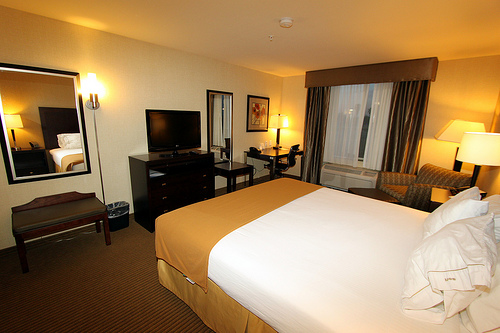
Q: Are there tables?
A: Yes, there is a table.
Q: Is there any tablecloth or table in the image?
A: Yes, there is a table.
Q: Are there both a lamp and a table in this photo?
A: Yes, there are both a table and a lamp.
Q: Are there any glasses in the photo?
A: No, there are no glasses.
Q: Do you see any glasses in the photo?
A: No, there are no glasses.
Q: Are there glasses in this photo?
A: No, there are no glasses.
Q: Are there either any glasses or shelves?
A: No, there are no glasses or shelves.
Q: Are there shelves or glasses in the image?
A: No, there are no glasses or shelves.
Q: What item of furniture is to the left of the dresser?
A: The piece of furniture is a table.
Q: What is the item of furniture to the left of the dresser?
A: The piece of furniture is a table.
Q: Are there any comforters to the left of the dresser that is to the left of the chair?
A: No, there is a table to the left of the dresser.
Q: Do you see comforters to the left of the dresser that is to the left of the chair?
A: No, there is a table to the left of the dresser.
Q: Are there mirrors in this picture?
A: Yes, there is a mirror.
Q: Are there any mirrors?
A: Yes, there is a mirror.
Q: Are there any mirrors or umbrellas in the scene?
A: Yes, there is a mirror.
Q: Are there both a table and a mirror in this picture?
A: Yes, there are both a mirror and a table.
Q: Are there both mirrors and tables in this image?
A: Yes, there are both a mirror and a table.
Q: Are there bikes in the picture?
A: No, there are no bikes.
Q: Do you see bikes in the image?
A: No, there are no bikes.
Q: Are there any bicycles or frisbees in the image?
A: No, there are no bicycles or frisbees.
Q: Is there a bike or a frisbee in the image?
A: No, there are no bikes or frisbees.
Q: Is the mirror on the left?
A: Yes, the mirror is on the left of the image.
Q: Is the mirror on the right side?
A: No, the mirror is on the left of the image.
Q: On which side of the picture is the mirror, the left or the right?
A: The mirror is on the left of the image.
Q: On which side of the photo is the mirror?
A: The mirror is on the left of the image.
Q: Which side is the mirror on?
A: The mirror is on the left of the image.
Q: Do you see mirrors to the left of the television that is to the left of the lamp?
A: Yes, there is a mirror to the left of the television.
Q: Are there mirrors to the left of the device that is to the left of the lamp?
A: Yes, there is a mirror to the left of the television.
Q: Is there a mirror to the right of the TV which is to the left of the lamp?
A: No, the mirror is to the left of the television.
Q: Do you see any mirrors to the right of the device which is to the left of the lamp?
A: No, the mirror is to the left of the television.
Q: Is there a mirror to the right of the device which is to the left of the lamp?
A: No, the mirror is to the left of the television.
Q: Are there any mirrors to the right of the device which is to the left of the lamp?
A: No, the mirror is to the left of the television.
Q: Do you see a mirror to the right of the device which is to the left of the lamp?
A: No, the mirror is to the left of the television.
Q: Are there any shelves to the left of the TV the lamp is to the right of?
A: No, there is a mirror to the left of the television.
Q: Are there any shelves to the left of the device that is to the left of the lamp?
A: No, there is a mirror to the left of the television.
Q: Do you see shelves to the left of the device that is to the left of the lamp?
A: No, there is a mirror to the left of the television.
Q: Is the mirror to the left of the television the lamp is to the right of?
A: Yes, the mirror is to the left of the TV.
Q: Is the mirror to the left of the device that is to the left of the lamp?
A: Yes, the mirror is to the left of the TV.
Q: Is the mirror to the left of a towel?
A: No, the mirror is to the left of the TV.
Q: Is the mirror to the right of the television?
A: No, the mirror is to the left of the television.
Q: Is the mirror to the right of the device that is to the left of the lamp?
A: No, the mirror is to the left of the television.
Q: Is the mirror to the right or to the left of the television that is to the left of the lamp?
A: The mirror is to the left of the TV.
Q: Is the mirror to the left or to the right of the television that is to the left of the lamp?
A: The mirror is to the left of the TV.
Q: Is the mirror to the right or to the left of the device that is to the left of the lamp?
A: The mirror is to the left of the TV.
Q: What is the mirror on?
A: The mirror is on the wall.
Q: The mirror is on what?
A: The mirror is on the wall.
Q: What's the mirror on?
A: The mirror is on the wall.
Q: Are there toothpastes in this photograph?
A: No, there are no toothpastes.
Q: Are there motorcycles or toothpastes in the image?
A: No, there are no toothpastes or motorcycles.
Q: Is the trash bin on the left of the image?
A: Yes, the trash bin is on the left of the image.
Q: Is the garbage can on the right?
A: No, the garbage can is on the left of the image.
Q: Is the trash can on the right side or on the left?
A: The trash can is on the left of the image.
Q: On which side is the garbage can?
A: The garbage can is on the left of the image.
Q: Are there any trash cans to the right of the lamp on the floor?
A: Yes, there is a trash can to the right of the lamp.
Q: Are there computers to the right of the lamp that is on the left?
A: No, there is a trash can to the right of the lamp.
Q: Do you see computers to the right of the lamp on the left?
A: No, there is a trash can to the right of the lamp.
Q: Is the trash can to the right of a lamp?
A: Yes, the trash can is to the right of a lamp.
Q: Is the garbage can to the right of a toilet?
A: No, the garbage can is to the right of a lamp.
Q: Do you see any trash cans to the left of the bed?
A: Yes, there is a trash can to the left of the bed.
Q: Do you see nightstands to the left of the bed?
A: No, there is a trash can to the left of the bed.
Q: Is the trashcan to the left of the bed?
A: Yes, the trashcan is to the left of the bed.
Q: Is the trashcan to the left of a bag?
A: No, the trashcan is to the left of the bed.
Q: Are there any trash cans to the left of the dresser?
A: Yes, there is a trash can to the left of the dresser.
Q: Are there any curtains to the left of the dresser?
A: No, there is a trash can to the left of the dresser.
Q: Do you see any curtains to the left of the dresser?
A: No, there is a trash can to the left of the dresser.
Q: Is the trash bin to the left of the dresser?
A: Yes, the trash bin is to the left of the dresser.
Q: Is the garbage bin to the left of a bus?
A: No, the garbage bin is to the left of the dresser.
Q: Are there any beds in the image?
A: Yes, there is a bed.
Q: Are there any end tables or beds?
A: Yes, there is a bed.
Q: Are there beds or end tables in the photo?
A: Yes, there is a bed.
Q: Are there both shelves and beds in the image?
A: No, there is a bed but no shelves.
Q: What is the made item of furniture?
A: The piece of furniture is a bed.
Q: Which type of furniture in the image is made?
A: The furniture is a bed.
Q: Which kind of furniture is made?
A: The furniture is a bed.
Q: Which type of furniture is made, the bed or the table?
A: The bed is made.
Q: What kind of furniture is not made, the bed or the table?
A: The table is not made.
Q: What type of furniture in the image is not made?
A: The furniture is a table.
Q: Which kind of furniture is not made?
A: The furniture is a table.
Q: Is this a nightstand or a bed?
A: This is a bed.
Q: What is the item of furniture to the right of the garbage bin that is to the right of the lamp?
A: The piece of furniture is a bed.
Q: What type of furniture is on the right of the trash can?
A: The piece of furniture is a bed.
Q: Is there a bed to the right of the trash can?
A: Yes, there is a bed to the right of the trash can.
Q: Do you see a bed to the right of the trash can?
A: Yes, there is a bed to the right of the trash can.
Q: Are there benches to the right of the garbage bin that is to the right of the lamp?
A: No, there is a bed to the right of the trash can.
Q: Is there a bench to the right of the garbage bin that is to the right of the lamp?
A: No, there is a bed to the right of the trash can.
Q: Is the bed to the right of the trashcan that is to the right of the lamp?
A: Yes, the bed is to the right of the trashcan.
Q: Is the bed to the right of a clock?
A: No, the bed is to the right of the trashcan.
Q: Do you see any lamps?
A: Yes, there is a lamp.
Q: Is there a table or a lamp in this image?
A: Yes, there is a lamp.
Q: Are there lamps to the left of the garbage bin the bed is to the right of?
A: Yes, there is a lamp to the left of the trash can.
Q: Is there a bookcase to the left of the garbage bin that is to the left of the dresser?
A: No, there is a lamp to the left of the garbage bin.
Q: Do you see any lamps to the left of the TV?
A: Yes, there is a lamp to the left of the TV.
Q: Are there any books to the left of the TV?
A: No, there is a lamp to the left of the TV.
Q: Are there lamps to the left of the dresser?
A: Yes, there is a lamp to the left of the dresser.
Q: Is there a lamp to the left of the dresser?
A: Yes, there is a lamp to the left of the dresser.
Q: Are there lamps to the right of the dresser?
A: No, the lamp is to the left of the dresser.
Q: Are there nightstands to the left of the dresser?
A: No, there is a lamp to the left of the dresser.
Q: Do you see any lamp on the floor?
A: Yes, there is a lamp on the floor.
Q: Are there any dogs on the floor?
A: No, there is a lamp on the floor.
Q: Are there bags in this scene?
A: No, there are no bags.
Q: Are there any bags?
A: No, there are no bags.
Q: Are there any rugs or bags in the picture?
A: No, there are no bags or rugs.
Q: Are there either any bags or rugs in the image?
A: No, there are no bags or rugs.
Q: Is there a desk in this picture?
A: Yes, there is a desk.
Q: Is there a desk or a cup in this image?
A: Yes, there is a desk.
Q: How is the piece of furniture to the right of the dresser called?
A: The piece of furniture is a desk.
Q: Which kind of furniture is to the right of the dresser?
A: The piece of furniture is a desk.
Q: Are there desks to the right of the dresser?
A: Yes, there is a desk to the right of the dresser.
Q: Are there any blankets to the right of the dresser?
A: No, there is a desk to the right of the dresser.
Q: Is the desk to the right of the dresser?
A: Yes, the desk is to the right of the dresser.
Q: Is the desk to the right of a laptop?
A: No, the desk is to the right of the dresser.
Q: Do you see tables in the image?
A: Yes, there is a table.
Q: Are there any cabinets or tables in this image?
A: Yes, there is a table.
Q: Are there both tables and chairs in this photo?
A: Yes, there are both a table and a chair.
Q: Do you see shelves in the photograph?
A: No, there are no shelves.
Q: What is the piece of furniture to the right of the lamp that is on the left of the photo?
A: The piece of furniture is a dresser.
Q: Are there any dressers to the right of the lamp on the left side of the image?
A: Yes, there is a dresser to the right of the lamp.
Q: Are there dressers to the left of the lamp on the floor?
A: No, the dresser is to the right of the lamp.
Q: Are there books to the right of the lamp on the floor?
A: No, there is a dresser to the right of the lamp.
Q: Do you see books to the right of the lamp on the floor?
A: No, there is a dresser to the right of the lamp.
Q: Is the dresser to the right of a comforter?
A: No, the dresser is to the right of the lamp.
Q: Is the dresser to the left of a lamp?
A: No, the dresser is to the right of a lamp.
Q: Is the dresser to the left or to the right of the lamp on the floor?
A: The dresser is to the right of the lamp.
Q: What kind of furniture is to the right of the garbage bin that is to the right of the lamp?
A: The piece of furniture is a dresser.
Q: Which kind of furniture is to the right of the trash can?
A: The piece of furniture is a dresser.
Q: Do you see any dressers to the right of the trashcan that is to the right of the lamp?
A: Yes, there is a dresser to the right of the garbage bin.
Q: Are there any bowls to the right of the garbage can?
A: No, there is a dresser to the right of the garbage can.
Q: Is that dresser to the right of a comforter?
A: No, the dresser is to the right of the trashcan.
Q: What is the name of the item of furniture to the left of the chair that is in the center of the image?
A: The piece of furniture is a dresser.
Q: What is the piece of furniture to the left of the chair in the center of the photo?
A: The piece of furniture is a dresser.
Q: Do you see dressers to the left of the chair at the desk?
A: Yes, there is a dresser to the left of the chair.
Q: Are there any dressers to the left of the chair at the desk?
A: Yes, there is a dresser to the left of the chair.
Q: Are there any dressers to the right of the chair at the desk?
A: No, the dresser is to the left of the chair.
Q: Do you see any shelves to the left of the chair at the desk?
A: No, there is a dresser to the left of the chair.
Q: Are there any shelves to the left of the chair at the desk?
A: No, there is a dresser to the left of the chair.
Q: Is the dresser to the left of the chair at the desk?
A: Yes, the dresser is to the left of the chair.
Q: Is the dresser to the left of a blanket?
A: No, the dresser is to the left of the chair.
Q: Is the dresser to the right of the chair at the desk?
A: No, the dresser is to the left of the chair.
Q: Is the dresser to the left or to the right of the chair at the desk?
A: The dresser is to the left of the chair.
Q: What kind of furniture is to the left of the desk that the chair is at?
A: The piece of furniture is a dresser.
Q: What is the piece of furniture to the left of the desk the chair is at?
A: The piece of furniture is a dresser.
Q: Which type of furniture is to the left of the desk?
A: The piece of furniture is a dresser.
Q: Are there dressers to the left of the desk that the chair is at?
A: Yes, there is a dresser to the left of the desk.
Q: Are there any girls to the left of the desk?
A: No, there is a dresser to the left of the desk.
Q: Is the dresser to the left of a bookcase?
A: No, the dresser is to the left of the desk.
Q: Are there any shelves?
A: No, there are no shelves.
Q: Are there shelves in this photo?
A: No, there are no shelves.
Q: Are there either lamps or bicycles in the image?
A: Yes, there is a lamp.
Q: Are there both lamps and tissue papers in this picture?
A: No, there is a lamp but no tissues.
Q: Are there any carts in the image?
A: No, there are no carts.